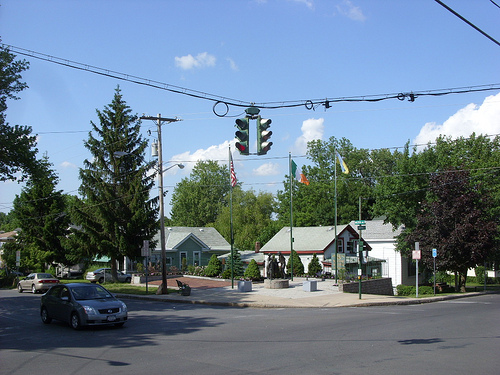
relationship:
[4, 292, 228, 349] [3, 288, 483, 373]
shadow on ground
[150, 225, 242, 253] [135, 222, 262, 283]
roof on house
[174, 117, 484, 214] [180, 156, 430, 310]
trees behind houses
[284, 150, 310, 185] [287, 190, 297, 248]
flag on pole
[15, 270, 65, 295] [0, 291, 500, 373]
car on road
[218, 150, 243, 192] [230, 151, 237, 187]
flag on flag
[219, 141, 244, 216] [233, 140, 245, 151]
light glowing red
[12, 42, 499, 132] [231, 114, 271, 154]
wire used to hang signals